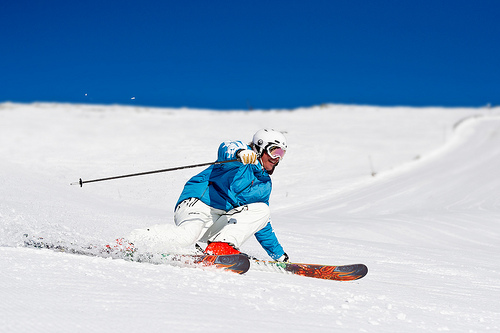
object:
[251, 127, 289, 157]
helmet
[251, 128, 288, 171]
head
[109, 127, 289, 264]
person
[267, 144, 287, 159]
goggles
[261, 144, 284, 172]
face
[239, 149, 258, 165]
glove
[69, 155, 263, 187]
ski pole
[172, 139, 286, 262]
jacket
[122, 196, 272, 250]
pants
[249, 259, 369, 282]
ski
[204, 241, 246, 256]
foot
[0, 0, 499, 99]
sky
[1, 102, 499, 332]
ground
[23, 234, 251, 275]
ski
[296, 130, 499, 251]
mark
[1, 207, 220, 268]
snow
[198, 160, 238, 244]
shadow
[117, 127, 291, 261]
body